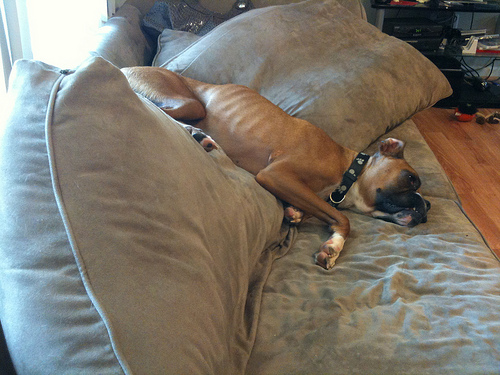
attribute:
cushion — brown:
[155, 0, 457, 160]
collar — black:
[325, 148, 370, 210]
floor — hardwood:
[412, 102, 498, 247]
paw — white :
[187, 124, 220, 153]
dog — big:
[109, 34, 433, 253]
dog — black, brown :
[102, 42, 499, 275]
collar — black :
[328, 150, 373, 205]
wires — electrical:
[460, 57, 498, 93]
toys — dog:
[448, 101, 499, 125]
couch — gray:
[0, 1, 499, 373]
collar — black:
[322, 147, 384, 214]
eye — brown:
[406, 178, 420, 187]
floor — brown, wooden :
[411, 105, 495, 257]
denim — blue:
[138, 1, 253, 52]